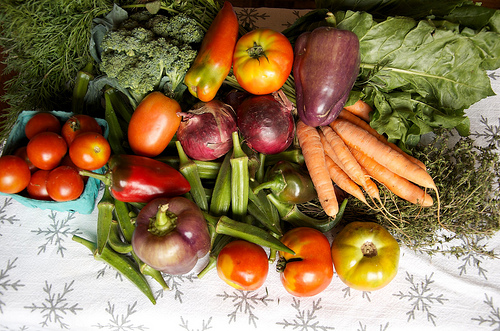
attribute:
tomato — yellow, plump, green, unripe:
[331, 220, 400, 292]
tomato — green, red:
[233, 29, 295, 97]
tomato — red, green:
[131, 91, 180, 155]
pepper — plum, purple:
[293, 20, 359, 128]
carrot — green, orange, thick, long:
[296, 118, 338, 218]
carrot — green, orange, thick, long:
[322, 125, 367, 183]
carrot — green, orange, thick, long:
[334, 121, 434, 187]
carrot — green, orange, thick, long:
[351, 149, 437, 208]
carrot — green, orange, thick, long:
[350, 97, 375, 120]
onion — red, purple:
[178, 99, 240, 162]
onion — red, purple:
[237, 92, 296, 149]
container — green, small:
[1, 103, 116, 208]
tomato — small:
[50, 162, 84, 202]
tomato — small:
[71, 133, 113, 166]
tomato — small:
[25, 110, 63, 139]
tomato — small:
[0, 154, 31, 195]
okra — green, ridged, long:
[230, 129, 254, 217]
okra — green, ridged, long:
[172, 141, 209, 208]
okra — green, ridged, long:
[218, 213, 297, 257]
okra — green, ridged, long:
[70, 237, 157, 305]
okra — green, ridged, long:
[93, 177, 116, 253]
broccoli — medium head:
[93, 7, 199, 96]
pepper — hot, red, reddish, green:
[189, 5, 240, 106]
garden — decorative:
[0, 2, 498, 306]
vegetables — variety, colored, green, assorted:
[6, 5, 499, 295]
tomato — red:
[277, 226, 334, 297]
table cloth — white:
[0, 155, 494, 329]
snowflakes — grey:
[20, 272, 87, 330]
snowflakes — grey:
[93, 294, 147, 329]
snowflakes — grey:
[214, 279, 279, 327]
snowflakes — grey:
[272, 299, 332, 330]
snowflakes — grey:
[388, 270, 451, 328]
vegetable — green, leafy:
[308, 13, 497, 134]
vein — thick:
[361, 62, 489, 91]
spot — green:
[192, 63, 216, 83]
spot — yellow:
[189, 55, 228, 96]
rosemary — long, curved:
[0, 4, 112, 136]